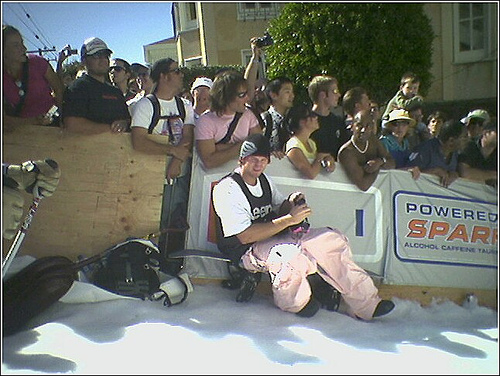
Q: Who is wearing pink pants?
A: The man sitting down.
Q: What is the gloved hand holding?
A: A ski pole.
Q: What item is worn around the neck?
A: A necklace.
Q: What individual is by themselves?
A: The skier.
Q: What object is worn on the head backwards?
A: A hat.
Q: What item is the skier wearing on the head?
A: A hat.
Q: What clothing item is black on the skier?
A: A vest.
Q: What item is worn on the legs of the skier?
A: Pants.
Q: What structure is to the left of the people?
A: A building.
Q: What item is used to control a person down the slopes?
A: A ski pole.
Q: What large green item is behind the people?
A: A tree.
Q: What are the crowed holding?
A: A long white sign.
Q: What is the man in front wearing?
A: Black tank top.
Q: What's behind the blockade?
A: Crowed of people.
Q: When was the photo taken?
A: Daytime.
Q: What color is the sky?
A: Blue.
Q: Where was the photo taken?
A: At a competition.